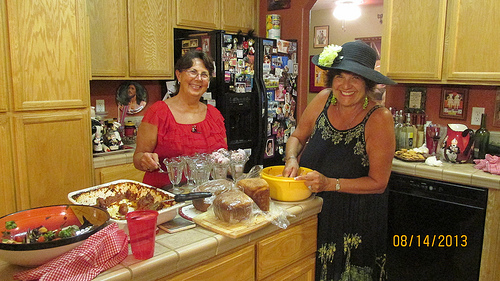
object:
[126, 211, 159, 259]
cup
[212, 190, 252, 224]
bread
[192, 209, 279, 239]
cutting board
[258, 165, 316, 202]
bowl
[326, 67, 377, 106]
head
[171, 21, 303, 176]
refrigerator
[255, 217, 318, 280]
drawer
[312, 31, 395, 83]
hat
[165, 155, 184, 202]
sundae dish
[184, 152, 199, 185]
sundae dish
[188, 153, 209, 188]
sundae dish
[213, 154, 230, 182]
sundae dish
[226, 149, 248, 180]
sundae dish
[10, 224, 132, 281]
hand towel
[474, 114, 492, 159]
wine bottle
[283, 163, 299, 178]
food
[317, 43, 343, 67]
flower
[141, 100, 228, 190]
shirt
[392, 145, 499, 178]
counter top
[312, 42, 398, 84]
hat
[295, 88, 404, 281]
dress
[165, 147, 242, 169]
top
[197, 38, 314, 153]
stickers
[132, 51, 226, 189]
lady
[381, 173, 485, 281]
dishwasher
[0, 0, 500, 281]
kitchen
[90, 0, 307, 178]
wall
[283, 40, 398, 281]
lady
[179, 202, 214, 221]
cutting board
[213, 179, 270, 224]
bread loaves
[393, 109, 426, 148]
liquor bottles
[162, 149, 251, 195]
dessert cups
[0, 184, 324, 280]
counter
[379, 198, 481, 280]
oven door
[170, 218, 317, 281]
drawers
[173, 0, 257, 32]
cabinets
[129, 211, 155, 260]
glass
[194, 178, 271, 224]
bread loaves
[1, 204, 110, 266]
bowl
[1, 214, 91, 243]
salad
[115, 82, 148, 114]
jesus painting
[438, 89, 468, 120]
painting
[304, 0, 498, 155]
wall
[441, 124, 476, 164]
pitcher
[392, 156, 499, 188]
counter